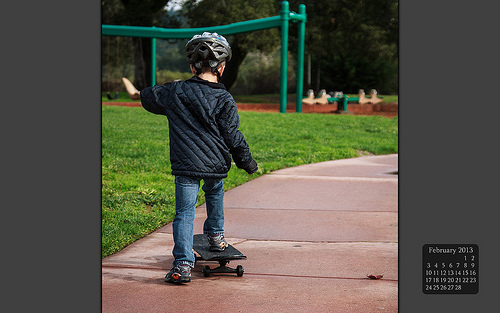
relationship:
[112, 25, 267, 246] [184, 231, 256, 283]
boy on a skateboard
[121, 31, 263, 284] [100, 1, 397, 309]
boy skateboarding in a park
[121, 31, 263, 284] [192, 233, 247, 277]
boy riding a black skateboard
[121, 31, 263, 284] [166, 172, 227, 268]
boy wearing blue jeans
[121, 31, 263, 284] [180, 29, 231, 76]
boy wearing a helmet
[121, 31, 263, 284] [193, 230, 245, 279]
boy on a skateboard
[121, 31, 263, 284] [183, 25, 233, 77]
boy wearing a helmet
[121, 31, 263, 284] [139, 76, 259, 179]
boy wearing a black jacket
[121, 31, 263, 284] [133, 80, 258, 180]
boy wearing a black jacket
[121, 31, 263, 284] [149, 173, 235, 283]
boy wearing jeans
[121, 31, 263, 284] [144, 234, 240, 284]
boy wearing sneakers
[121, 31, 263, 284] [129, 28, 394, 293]
boy in outdoors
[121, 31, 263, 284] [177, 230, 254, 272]
boy on skateboard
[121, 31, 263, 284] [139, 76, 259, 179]
boy wearing black jacket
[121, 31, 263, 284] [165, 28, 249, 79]
boy wearing helmet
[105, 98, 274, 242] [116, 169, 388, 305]
grass next to sidewalk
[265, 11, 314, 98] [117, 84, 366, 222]
posts in grass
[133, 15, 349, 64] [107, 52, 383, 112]
trees behind playground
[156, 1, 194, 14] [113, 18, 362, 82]
sky behind trees